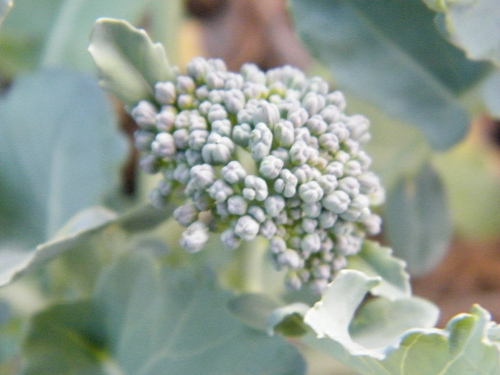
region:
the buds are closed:
[18, 8, 498, 363]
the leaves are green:
[1, 0, 498, 362]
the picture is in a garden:
[2, 8, 495, 373]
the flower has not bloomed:
[131, 52, 386, 289]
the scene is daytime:
[1, 5, 496, 372]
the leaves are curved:
[11, 10, 495, 367]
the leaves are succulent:
[5, 3, 499, 370]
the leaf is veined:
[89, 241, 309, 369]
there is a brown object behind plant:
[188, 1, 316, 71]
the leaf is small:
[85, 10, 180, 117]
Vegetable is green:
[11, 7, 493, 365]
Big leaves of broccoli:
[11, 258, 485, 373]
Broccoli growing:
[128, 51, 396, 291]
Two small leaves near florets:
[81, 14, 429, 305]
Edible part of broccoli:
[125, 51, 390, 298]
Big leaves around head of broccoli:
[0, 4, 495, 374]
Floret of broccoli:
[240, 170, 271, 205]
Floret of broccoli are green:
[137, 55, 389, 286]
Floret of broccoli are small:
[128, 54, 392, 288]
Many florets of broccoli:
[115, 51, 402, 306]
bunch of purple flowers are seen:
[188, 86, 330, 228]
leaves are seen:
[61, 229, 180, 338]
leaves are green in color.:
[47, 203, 206, 337]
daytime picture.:
[30, 40, 417, 316]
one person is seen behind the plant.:
[211, 12, 282, 47]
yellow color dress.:
[167, 13, 207, 58]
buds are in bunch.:
[166, 83, 342, 248]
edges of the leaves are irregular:
[10, 231, 115, 311]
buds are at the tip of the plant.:
[107, 35, 405, 305]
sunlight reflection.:
[108, 13, 398, 224]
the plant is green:
[0, 2, 499, 373]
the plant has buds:
[134, 55, 384, 293]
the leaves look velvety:
[1, 1, 498, 373]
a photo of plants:
[0, 1, 498, 372]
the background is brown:
[181, 1, 496, 325]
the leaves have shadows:
[0, 1, 497, 373]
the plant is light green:
[0, 0, 499, 372]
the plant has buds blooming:
[125, 55, 386, 288]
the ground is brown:
[0, 0, 497, 374]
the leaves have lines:
[0, 1, 497, 373]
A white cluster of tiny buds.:
[126, 56, 380, 289]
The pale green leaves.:
[1, 269, 499, 374]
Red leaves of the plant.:
[424, 233, 498, 305]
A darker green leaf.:
[356, 18, 472, 127]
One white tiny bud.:
[251, 122, 273, 159]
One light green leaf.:
[80, 18, 165, 98]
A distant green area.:
[3, 33, 35, 80]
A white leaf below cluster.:
[310, 263, 380, 333]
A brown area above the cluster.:
[184, 0, 225, 20]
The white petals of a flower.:
[435, 0, 499, 119]